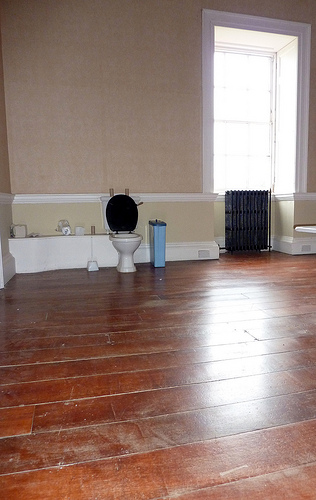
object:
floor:
[176, 462, 315, 498]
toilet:
[100, 195, 143, 274]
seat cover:
[106, 195, 140, 233]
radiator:
[223, 188, 272, 251]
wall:
[0, 1, 316, 259]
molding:
[2, 192, 316, 207]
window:
[214, 40, 278, 195]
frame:
[199, 8, 313, 195]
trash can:
[147, 220, 168, 268]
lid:
[149, 218, 169, 228]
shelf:
[7, 234, 112, 274]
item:
[12, 223, 28, 239]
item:
[28, 230, 40, 237]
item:
[54, 217, 73, 235]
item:
[74, 225, 89, 237]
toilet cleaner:
[86, 233, 100, 272]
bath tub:
[294, 225, 315, 235]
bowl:
[110, 232, 144, 255]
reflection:
[200, 275, 273, 426]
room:
[2, 1, 316, 500]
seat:
[108, 233, 144, 247]